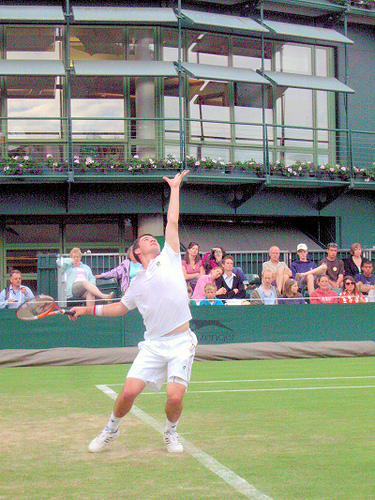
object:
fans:
[0, 242, 375, 306]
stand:
[0, 304, 375, 342]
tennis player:
[13, 169, 201, 451]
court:
[0, 356, 375, 499]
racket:
[16, 295, 76, 321]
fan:
[291, 243, 316, 295]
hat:
[296, 242, 308, 251]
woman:
[339, 276, 368, 303]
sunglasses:
[344, 282, 355, 285]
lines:
[186, 375, 375, 393]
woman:
[56, 247, 114, 305]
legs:
[72, 280, 114, 307]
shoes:
[87, 425, 184, 453]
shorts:
[125, 328, 198, 389]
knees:
[117, 385, 185, 406]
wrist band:
[94, 305, 103, 317]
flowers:
[0, 153, 374, 179]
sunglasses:
[327, 242, 339, 248]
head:
[326, 242, 338, 258]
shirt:
[121, 241, 193, 341]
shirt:
[339, 291, 367, 304]